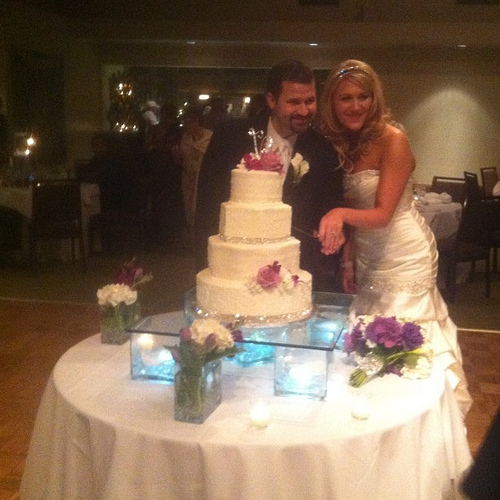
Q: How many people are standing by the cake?
A: Two.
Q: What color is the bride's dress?
A: White.